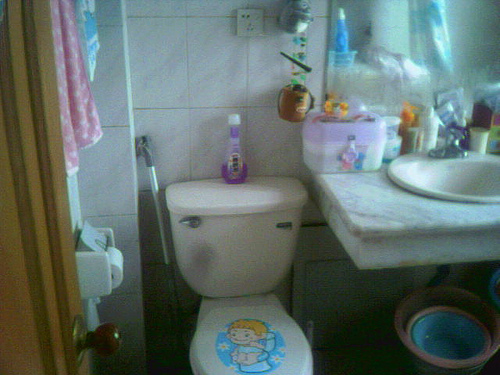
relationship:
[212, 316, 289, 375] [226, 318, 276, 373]
picture of a child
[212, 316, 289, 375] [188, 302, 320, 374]
picture on a toilet lid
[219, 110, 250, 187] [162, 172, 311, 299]
cleaning liquid on a toilet tank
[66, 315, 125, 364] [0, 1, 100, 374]
handle of a door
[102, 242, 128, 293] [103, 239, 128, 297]
roll of toilet paper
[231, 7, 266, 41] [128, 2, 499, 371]
outlet cover on wall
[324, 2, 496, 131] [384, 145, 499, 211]
mirror behind a sink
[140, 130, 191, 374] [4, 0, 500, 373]
mop in corner of bathroom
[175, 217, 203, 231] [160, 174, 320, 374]
handle on a toilet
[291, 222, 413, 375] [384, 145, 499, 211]
vent under a sink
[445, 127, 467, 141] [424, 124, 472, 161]
handle of a faucet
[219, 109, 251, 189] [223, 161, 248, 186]
bottle has liquid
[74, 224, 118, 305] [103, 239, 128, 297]
holder of toilet paper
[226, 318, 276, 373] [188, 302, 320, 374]
child on toilet lid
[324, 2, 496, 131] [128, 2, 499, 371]
mirror on wall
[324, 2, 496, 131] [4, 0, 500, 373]
mirror in bathroom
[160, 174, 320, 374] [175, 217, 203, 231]
toilet has handle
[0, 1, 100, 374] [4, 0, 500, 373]
door of bathroom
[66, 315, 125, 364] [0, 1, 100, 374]
handle of door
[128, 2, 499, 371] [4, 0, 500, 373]
wall in a bathroom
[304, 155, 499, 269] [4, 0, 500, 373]
counter in bathroom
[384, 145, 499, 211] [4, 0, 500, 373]
sink in a bathroom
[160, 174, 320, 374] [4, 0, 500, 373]
toilet in bathroom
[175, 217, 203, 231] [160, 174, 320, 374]
handle on toilet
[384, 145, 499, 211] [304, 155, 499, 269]
sink in counter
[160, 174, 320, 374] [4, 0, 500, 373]
toilet in a bathroom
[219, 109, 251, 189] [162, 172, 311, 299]
bottle on a toilet tank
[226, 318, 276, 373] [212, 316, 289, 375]
child on a picture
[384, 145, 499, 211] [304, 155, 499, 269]
sink on a counter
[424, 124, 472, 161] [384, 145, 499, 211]
faucet on a sink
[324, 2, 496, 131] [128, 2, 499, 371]
mirror on a wall